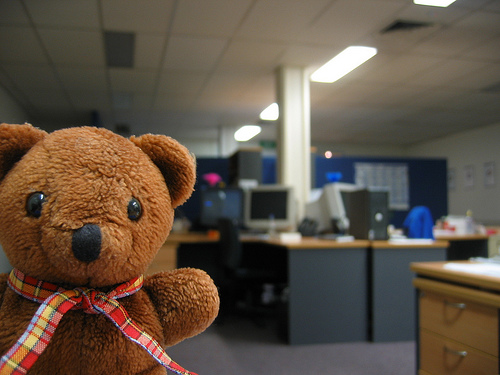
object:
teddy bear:
[1, 124, 220, 375]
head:
[0, 120, 197, 288]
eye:
[25, 191, 45, 217]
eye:
[128, 198, 142, 221]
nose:
[71, 224, 101, 263]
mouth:
[34, 226, 135, 286]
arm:
[142, 267, 220, 346]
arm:
[0, 272, 12, 309]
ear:
[125, 132, 199, 205]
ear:
[0, 122, 49, 179]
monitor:
[243, 187, 292, 228]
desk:
[242, 232, 370, 345]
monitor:
[306, 182, 354, 231]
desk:
[370, 239, 449, 342]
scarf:
[0, 267, 197, 374]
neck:
[6, 267, 146, 316]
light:
[311, 45, 376, 85]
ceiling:
[1, 1, 500, 155]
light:
[259, 102, 279, 121]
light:
[233, 125, 261, 141]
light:
[414, 0, 457, 8]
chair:
[217, 217, 278, 326]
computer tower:
[348, 188, 388, 241]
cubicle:
[263, 154, 447, 229]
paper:
[463, 163, 473, 189]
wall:
[406, 120, 499, 225]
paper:
[446, 166, 455, 188]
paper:
[482, 160, 495, 185]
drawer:
[419, 289, 500, 355]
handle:
[444, 300, 465, 310]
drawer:
[417, 327, 498, 374]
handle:
[444, 344, 466, 354]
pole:
[276, 65, 310, 222]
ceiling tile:
[161, 32, 230, 75]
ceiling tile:
[35, 26, 107, 69]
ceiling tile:
[409, 57, 491, 91]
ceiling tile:
[156, 68, 208, 97]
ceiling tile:
[57, 63, 109, 103]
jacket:
[401, 206, 433, 238]